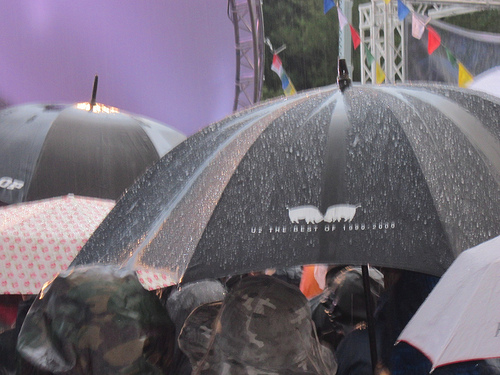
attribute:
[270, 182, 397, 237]
image — black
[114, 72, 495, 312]
umbrella — pink and white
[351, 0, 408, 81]
steel — large, white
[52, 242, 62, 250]
pattern — white, pink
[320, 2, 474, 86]
flags — colorful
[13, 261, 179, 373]
material — decorative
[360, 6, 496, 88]
structure — metal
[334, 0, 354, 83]
structure — metal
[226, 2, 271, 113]
structure — metal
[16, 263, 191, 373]
cap — green and brown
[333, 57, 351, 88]
point — tall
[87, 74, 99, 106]
point — tall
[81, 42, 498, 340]
material — decorative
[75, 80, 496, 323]
umbrella — white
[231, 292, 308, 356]
cup — brown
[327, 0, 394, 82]
string — colored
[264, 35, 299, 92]
string — colored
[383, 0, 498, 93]
string — colored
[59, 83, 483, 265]
umbrella — large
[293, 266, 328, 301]
clothing — orange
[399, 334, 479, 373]
trim — red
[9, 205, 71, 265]
pattern — red